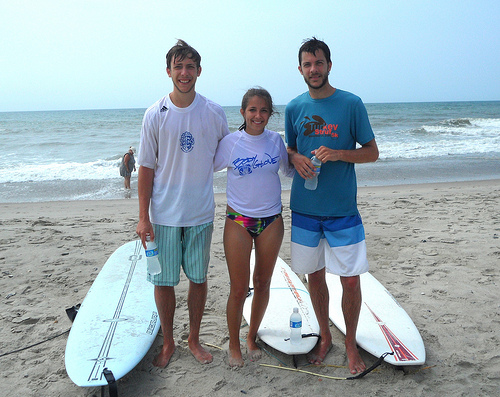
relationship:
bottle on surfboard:
[288, 303, 300, 339] [245, 244, 324, 356]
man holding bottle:
[283, 36, 379, 375] [291, 145, 335, 202]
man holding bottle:
[283, 36, 379, 375] [306, 135, 326, 222]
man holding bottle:
[251, 21, 408, 242] [285, 137, 347, 200]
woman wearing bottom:
[210, 82, 295, 368] [220, 207, 283, 237]